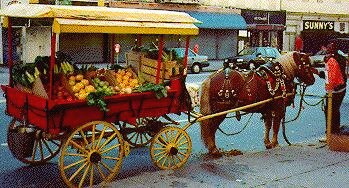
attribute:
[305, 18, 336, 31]
sign — black and white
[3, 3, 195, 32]
roof — yellow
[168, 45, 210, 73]
car — parked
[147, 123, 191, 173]
wheel — wooden 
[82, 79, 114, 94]
apples — green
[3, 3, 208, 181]
wagon — red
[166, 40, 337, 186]
horse — brown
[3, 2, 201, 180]
cart — mobile, fruit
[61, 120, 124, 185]
wheel — back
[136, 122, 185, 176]
wheel — is smaller than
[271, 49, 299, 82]
mane — blond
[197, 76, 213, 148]
tail — blond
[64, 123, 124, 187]
wheel — cart, wooden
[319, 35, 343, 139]
man — standing 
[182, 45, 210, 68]
car — grey, parked